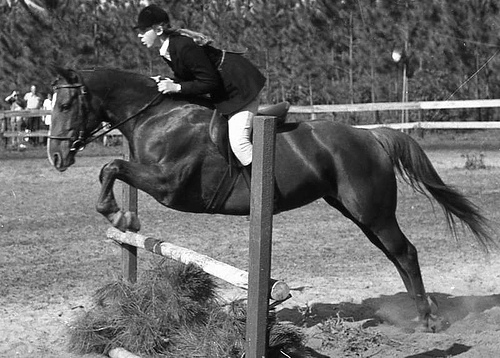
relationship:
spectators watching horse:
[6, 86, 60, 116] [39, 62, 496, 334]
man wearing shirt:
[22, 83, 44, 143] [25, 92, 44, 111]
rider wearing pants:
[136, 6, 268, 183] [228, 96, 261, 168]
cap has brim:
[132, 5, 172, 33] [129, 23, 146, 31]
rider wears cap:
[136, 6, 268, 183] [132, 5, 172, 33]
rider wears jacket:
[136, 6, 268, 183] [159, 32, 265, 118]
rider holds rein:
[136, 6, 268, 183] [68, 80, 175, 150]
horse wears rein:
[39, 62, 496, 334] [68, 80, 175, 150]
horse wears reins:
[39, 62, 496, 334] [68, 80, 175, 150]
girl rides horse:
[136, 6, 268, 183] [39, 62, 496, 334]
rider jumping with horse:
[136, 6, 268, 183] [39, 62, 496, 334]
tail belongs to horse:
[369, 125, 500, 258] [39, 62, 496, 334]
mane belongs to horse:
[68, 69, 161, 113] [39, 62, 496, 334]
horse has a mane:
[39, 62, 496, 334] [68, 69, 161, 113]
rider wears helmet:
[136, 6, 268, 183] [132, 5, 172, 33]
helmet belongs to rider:
[132, 5, 172, 33] [136, 6, 268, 183]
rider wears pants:
[136, 6, 268, 183] [228, 96, 261, 168]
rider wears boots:
[136, 6, 268, 183] [239, 161, 278, 223]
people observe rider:
[5, 86, 56, 148] [136, 6, 268, 183]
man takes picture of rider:
[4, 90, 26, 146] [136, 6, 268, 183]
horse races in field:
[39, 62, 496, 334] [0, 143, 499, 357]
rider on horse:
[136, 6, 268, 183] [39, 62, 496, 334]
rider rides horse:
[136, 6, 268, 183] [39, 62, 496, 334]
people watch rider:
[5, 86, 56, 148] [136, 6, 268, 183]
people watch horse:
[5, 86, 56, 148] [39, 62, 496, 334]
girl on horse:
[136, 6, 268, 183] [39, 62, 496, 334]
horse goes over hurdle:
[39, 62, 496, 334] [104, 114, 280, 357]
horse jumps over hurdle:
[39, 62, 496, 334] [104, 114, 280, 357]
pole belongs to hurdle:
[244, 115, 279, 357] [104, 114, 280, 357]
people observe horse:
[5, 86, 56, 148] [39, 62, 496, 334]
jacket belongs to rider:
[159, 32, 265, 118] [136, 6, 268, 183]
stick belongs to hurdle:
[105, 219, 292, 305] [104, 114, 280, 357]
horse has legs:
[39, 62, 496, 334] [94, 156, 449, 332]